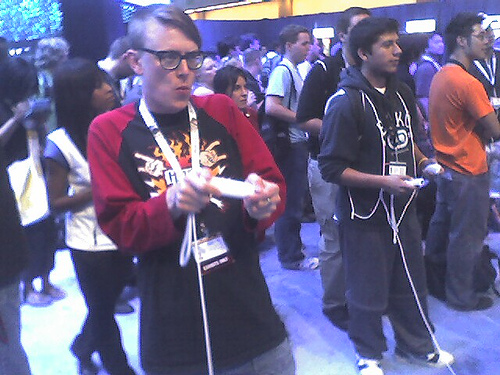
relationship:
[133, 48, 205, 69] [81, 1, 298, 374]
glasses on boy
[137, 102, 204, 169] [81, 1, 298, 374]
lanyard on boy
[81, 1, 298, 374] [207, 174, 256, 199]
boy has a controller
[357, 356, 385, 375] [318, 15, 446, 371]
shoe on man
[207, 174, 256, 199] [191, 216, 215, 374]
controller has a cord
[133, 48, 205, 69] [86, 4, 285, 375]
glasses on boy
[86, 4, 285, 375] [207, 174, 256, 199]
boy holding controller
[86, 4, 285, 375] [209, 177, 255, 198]
boy playing a controller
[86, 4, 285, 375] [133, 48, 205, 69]
boy wearing glasses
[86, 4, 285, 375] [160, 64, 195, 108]
boy making a face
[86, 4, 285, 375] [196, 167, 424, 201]
boy playing games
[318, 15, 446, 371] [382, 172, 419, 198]
man has a hand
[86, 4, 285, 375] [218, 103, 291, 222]
boy has an arm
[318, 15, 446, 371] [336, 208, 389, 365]
man has a leg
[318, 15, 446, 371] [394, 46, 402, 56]
man has a nose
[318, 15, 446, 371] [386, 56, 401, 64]
man has a mouth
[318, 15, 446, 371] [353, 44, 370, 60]
man has an ear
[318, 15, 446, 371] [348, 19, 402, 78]
man has a head